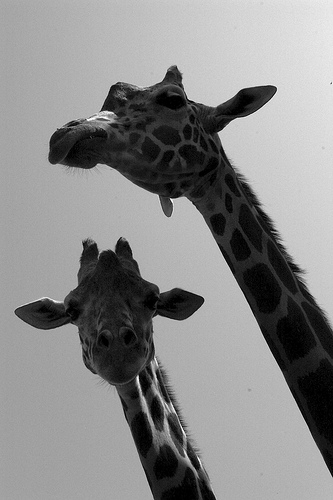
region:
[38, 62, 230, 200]
head of a giraffe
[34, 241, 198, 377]
head of a giraffe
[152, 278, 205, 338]
ear of a giraffe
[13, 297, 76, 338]
ear of a giraffe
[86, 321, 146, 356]
nose of a giraffe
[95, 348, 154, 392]
mouth of a giraffe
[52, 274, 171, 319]
eyes of a giraffe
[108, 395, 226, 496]
neck of a giraffe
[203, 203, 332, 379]
neck of a giraffe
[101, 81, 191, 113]
eyes of a giraffe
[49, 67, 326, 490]
two animals in the photo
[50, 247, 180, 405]
smaller animal looking at camera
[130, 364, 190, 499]
spots on giraffe neck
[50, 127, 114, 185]
dark mouth on animal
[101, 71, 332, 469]
giraffe is taller than smaller one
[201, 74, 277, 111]
ears of giraffe are black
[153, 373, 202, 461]
fur on back of giraffe neck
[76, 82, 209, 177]
face has black spots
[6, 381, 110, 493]
background is gray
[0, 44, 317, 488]
photo is in black and white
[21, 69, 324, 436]
this is a giraffe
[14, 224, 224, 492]
this is a giraffe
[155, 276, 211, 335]
this is an ear of a giraffe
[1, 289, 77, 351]
this is an ear of a giraffe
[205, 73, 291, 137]
this is an ear of a giraffe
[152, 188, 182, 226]
this is an ear of a giraffe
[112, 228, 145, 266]
this is a horn of a giraffe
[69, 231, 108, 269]
this is a horn of a giraffe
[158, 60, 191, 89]
this is a horn of a giraffe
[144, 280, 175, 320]
this is an eye of a giraffe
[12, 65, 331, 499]
two giraffes' heads and necks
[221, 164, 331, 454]
the neck of a giraffe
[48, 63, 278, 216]
the head of a giraffe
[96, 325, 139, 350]
the nostrils of a giraffe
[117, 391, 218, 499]
the giraffe's spotted neck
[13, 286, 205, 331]
the giraffe's two ears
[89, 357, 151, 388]
the mouth of a giraffe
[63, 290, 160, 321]
the giraffe's two eyes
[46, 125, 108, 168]
the giraffe's two lips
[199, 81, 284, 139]
the giraffe's left ear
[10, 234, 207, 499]
giraffe looking down from above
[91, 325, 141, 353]
giraffe has two large nostrils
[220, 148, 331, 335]
giraffe has a fuzzy mane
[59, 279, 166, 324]
giraffe has two eyes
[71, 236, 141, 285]
giraffe has horns on its head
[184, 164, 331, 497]
giraffe has a long neck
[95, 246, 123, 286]
giraffe has a bump on its head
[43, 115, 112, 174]
the giraffe's mouth is closed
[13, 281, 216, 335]
the giraffe has two ears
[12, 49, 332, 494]
a couple of giraffes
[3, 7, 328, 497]
a gray sky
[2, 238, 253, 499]
a giraffe looking at camera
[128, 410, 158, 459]
a spot on the giraffe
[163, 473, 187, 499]
a spot on the giraffe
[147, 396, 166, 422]
a spot on the giraffe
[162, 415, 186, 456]
a spot on the giraffe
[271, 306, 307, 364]
a spot on the giraffe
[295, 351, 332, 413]
a spot on the giraffe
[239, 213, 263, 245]
a spot on the giraffe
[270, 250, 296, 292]
a spot on the giraffe